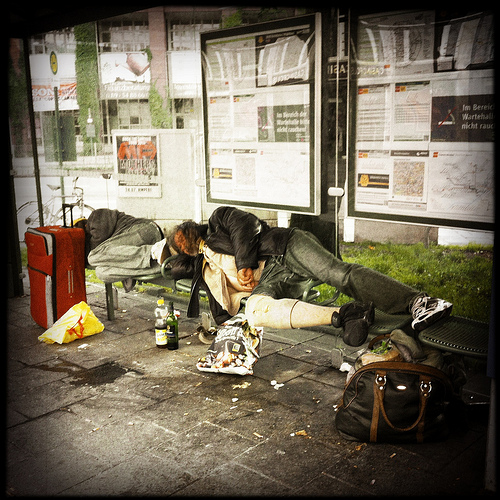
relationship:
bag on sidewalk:
[337, 362, 464, 445] [1, 272, 484, 500]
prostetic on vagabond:
[246, 294, 337, 329] [164, 205, 453, 346]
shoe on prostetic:
[332, 301, 374, 349] [246, 294, 337, 329]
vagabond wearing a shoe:
[164, 205, 453, 346] [332, 301, 374, 349]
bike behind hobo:
[18, 174, 94, 240] [76, 208, 170, 279]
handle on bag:
[375, 387, 405, 432] [337, 362, 464, 445]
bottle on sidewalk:
[167, 298, 181, 350] [1, 272, 484, 500]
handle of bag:
[60, 201, 76, 229] [27, 225, 88, 331]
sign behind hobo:
[114, 128, 164, 200] [76, 208, 170, 279]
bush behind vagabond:
[341, 238, 493, 323] [164, 205, 453, 346]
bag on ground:
[337, 362, 464, 445] [1, 272, 484, 500]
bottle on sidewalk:
[153, 299, 169, 349] [1, 272, 484, 500]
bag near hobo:
[27, 225, 88, 331] [76, 208, 170, 279]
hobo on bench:
[76, 208, 170, 279] [421, 310, 495, 363]